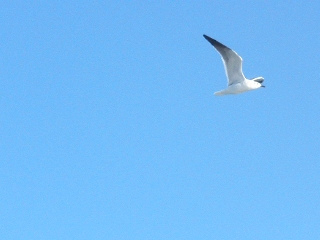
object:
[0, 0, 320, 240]
sky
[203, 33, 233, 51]
tip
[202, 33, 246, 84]
wing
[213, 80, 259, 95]
body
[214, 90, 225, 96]
tail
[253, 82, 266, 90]
head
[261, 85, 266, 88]
beak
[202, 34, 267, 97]
bird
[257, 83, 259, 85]
eye